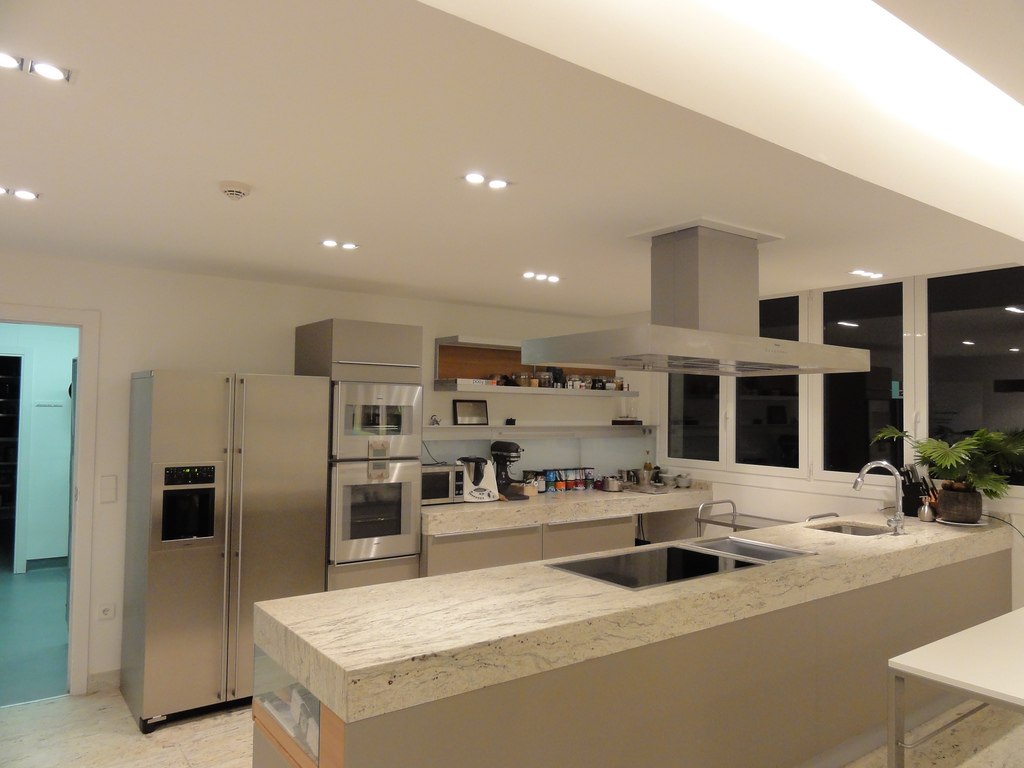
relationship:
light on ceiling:
[424, 140, 516, 221] [419, 114, 556, 237]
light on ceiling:
[495, 243, 573, 294] [492, 231, 608, 315]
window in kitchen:
[645, 366, 721, 449] [27, 164, 929, 716]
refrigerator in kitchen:
[115, 349, 324, 599] [27, 164, 929, 716]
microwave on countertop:
[419, 462, 470, 504] [422, 482, 710, 536]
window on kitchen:
[664, 358, 722, 460] [5, 3, 1021, 763]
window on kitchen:
[732, 295, 796, 469] [5, 3, 1021, 763]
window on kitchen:
[819, 269, 902, 467] [5, 3, 1021, 763]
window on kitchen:
[928, 269, 1018, 460] [5, 3, 1021, 763]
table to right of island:
[887, 599, 1021, 765] [248, 506, 1007, 762]